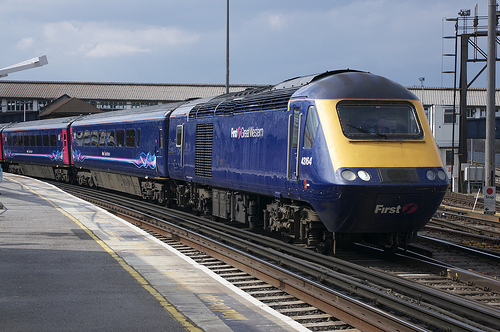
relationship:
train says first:
[9, 57, 454, 257] [372, 201, 401, 219]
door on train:
[283, 98, 304, 181] [168, 69, 453, 255]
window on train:
[326, 95, 431, 147] [9, 57, 454, 257]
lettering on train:
[222, 120, 268, 140] [69, 49, 451, 265]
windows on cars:
[2, 106, 327, 151] [3, 69, 338, 226]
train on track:
[168, 69, 453, 255] [60, 180, 497, 330]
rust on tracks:
[130, 211, 420, 330] [285, 254, 415, 311]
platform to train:
[10, 181, 288, 328] [9, 57, 454, 257]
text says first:
[367, 200, 414, 215] [372, 202, 402, 214]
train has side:
[28, 76, 463, 256] [14, 99, 329, 221]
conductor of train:
[368, 112, 395, 137] [9, 57, 454, 257]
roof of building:
[0, 78, 270, 102] [0, 78, 498, 176]